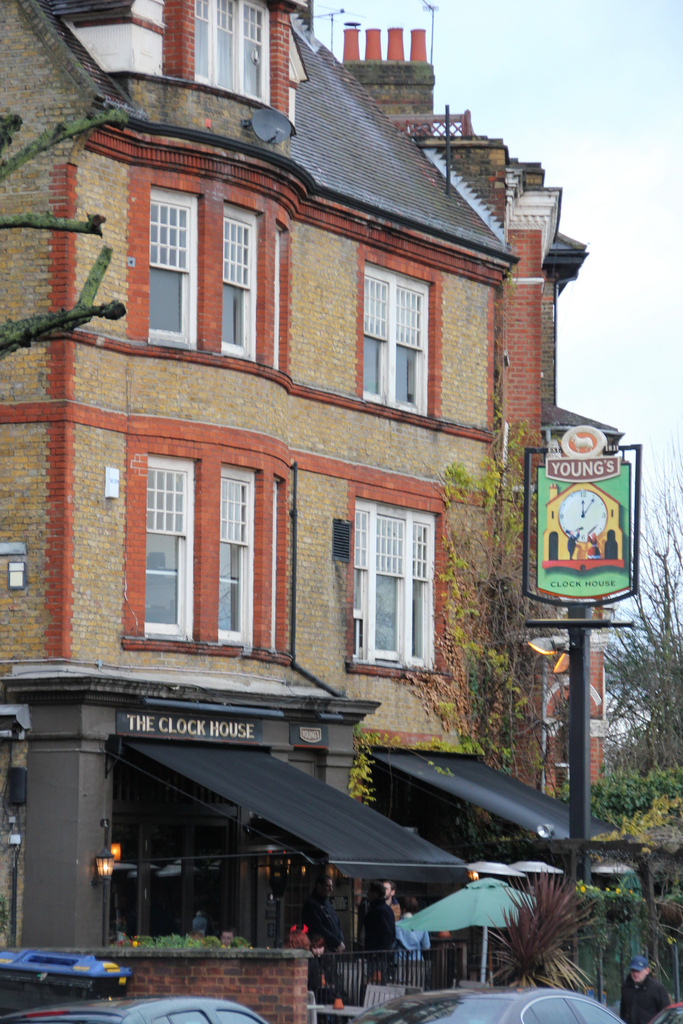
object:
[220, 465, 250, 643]
window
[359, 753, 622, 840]
awning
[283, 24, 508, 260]
roof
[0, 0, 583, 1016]
building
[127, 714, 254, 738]
lettering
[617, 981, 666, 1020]
shirt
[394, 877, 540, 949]
umbrella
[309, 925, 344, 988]
railing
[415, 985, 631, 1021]
car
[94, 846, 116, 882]
light fixture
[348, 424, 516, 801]
ivy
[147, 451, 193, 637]
window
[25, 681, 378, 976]
entryway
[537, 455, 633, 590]
sign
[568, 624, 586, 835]
post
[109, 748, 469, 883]
awning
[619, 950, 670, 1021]
man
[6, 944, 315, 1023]
wall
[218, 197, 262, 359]
window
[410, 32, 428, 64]
smoke stack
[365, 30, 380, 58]
smoke stack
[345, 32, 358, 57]
smoke stack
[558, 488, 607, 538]
clock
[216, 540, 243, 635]
glass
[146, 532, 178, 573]
glass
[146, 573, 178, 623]
glass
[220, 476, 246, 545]
glass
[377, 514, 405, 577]
glass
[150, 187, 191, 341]
window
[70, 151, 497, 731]
wall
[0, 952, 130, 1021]
car